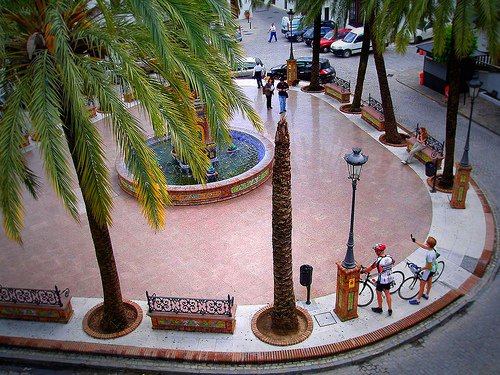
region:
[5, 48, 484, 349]
park in a city type setting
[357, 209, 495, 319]
bicyclists on the side walk at the park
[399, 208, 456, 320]
bicyclist taking pictures of the fountain in the park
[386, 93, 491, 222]
woman sitting on a bench in the park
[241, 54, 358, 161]
three people wandering around the park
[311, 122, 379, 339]
street light in the round park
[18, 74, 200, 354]
palm tree decorating the park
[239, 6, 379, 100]
cars parked outside of the park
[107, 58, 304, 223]
fountain in the center of the park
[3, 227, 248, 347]
park benches sitting at the side of the round park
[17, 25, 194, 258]
The tree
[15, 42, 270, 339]
The tree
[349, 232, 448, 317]
two people with bicycles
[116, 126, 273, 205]
a colorful fountain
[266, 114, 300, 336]
a tree trunk with no top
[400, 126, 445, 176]
woman sitting on bench alone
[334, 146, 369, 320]
lamp post next to biker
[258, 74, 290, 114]
people standing next to fountain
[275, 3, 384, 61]
cars parked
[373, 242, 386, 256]
red helmet of biker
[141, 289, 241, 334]
an empty bench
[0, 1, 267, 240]
giant palm tree leaves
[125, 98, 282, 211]
a fountain near benches.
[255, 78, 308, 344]
a headless palm tree.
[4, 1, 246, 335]
a leafy green palm tree.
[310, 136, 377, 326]
a street light.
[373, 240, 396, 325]
a person standing.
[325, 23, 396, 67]
a car on a street.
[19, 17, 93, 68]
a head of a palm tree.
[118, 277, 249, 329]
a bench near a fountain.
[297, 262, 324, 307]
a sign near a tree.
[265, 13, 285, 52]
a man crossing a street.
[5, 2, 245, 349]
Tall palm tree with fronds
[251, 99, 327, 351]
Palm tree without fronds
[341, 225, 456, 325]
Two bicyclists with their bikes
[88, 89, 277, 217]
Large fountain with water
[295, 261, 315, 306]
Small metal trash receptacle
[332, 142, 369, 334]
Tall decorative light post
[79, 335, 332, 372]
Brick work around the edges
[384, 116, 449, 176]
Woman sitting on a park bench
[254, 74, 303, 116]
Two people walk across a plaza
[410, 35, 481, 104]
Small building with orange posts